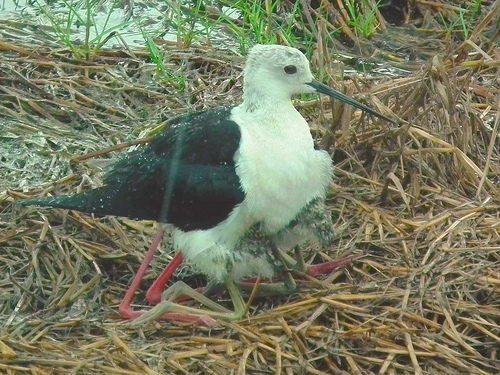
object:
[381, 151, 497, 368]
vegetation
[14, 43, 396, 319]
bird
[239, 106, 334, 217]
chest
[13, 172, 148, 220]
tail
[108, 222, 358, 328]
legs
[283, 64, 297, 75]
eye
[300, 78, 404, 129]
beak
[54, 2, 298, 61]
grass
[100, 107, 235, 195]
wing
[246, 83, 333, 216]
feathers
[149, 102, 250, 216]
feathers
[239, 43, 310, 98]
head